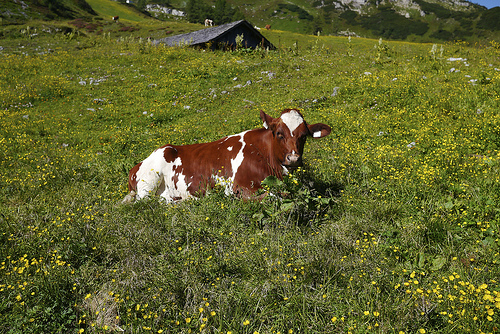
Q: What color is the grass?
A: Green.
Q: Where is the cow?
A: Field.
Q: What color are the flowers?
A: Yellow.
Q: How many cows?
A: One.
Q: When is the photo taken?
A: Daytime.